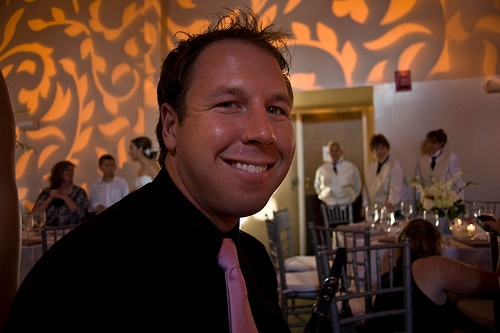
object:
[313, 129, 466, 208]
three servers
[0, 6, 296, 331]
man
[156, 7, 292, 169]
haircut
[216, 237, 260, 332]
tie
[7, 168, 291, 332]
shirt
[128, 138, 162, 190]
lady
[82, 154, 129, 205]
people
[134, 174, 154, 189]
top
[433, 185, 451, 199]
flower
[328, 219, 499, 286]
table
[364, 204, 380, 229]
goblets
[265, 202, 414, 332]
empty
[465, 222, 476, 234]
candles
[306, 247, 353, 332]
purse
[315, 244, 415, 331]
chair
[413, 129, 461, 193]
server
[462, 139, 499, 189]
corner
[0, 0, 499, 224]
lighted decorations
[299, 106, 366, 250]
door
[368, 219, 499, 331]
woman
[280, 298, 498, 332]
floor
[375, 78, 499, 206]
wall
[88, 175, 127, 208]
white shirt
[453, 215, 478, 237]
two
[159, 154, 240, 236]
neck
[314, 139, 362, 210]
waiter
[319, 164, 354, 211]
vest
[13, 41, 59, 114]
design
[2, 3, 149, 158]
walls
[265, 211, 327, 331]
chairs